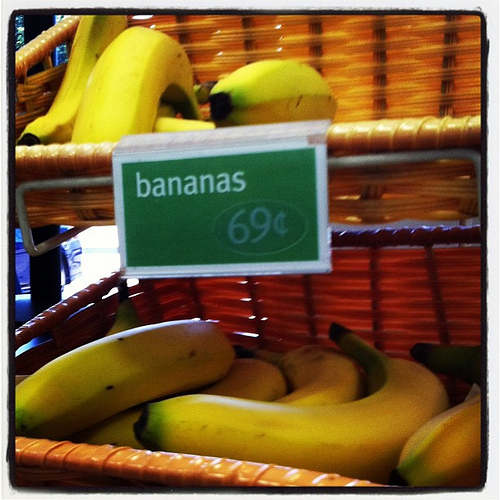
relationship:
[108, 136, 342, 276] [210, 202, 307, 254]
sign shows price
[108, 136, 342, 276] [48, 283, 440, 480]
sign for bananas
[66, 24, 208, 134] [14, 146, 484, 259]
banana on rack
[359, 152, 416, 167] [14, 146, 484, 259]
pole on rack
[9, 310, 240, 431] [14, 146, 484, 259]
banana on rack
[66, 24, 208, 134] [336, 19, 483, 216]
banana in basket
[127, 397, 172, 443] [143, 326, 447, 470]
end of banana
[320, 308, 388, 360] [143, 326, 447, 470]
stem of banana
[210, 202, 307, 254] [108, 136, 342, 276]
price on sign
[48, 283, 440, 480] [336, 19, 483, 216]
bananas in basket